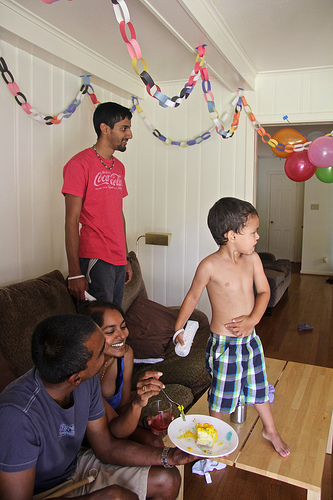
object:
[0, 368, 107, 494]
shirt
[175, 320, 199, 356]
controller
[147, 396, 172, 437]
glass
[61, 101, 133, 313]
man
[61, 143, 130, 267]
shirt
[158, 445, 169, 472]
wristwatch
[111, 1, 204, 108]
paper streamers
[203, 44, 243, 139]
paper streamers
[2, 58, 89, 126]
paper streamers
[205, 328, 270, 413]
shorts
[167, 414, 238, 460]
plate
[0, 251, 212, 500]
couch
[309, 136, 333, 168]
decoration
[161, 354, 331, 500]
table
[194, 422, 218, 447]
cake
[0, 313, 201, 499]
man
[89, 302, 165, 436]
woman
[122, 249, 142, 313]
pillow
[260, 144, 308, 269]
door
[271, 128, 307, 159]
balloon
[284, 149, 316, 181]
balloon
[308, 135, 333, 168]
balloon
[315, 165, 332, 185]
balloon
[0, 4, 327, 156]
decorations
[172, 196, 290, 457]
boy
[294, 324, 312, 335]
shoe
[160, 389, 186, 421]
fork